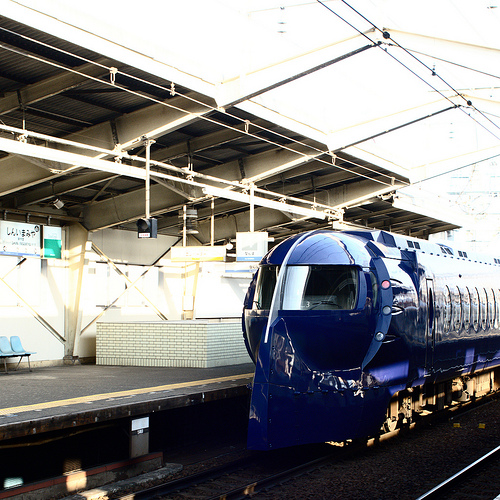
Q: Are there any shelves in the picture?
A: No, there are no shelves.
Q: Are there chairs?
A: Yes, there is a chair.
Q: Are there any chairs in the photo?
A: Yes, there is a chair.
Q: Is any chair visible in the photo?
A: Yes, there is a chair.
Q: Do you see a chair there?
A: Yes, there is a chair.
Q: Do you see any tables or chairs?
A: Yes, there is a chair.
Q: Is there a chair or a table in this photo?
A: Yes, there is a chair.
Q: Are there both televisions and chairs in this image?
A: No, there is a chair but no televisions.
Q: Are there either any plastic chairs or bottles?
A: Yes, there is a plastic chair.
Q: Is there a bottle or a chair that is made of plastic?
A: Yes, the chair is made of plastic.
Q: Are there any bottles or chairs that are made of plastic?
A: Yes, the chair is made of plastic.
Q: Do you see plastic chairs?
A: Yes, there is a chair that is made of plastic.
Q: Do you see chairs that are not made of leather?
A: Yes, there is a chair that is made of plastic.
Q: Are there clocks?
A: No, there are no clocks.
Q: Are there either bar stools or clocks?
A: No, there are no clocks or bar stools.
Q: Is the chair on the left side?
A: Yes, the chair is on the left of the image.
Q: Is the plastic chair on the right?
A: No, the chair is on the left of the image.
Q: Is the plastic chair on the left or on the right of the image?
A: The chair is on the left of the image.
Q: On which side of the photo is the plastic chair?
A: The chair is on the left of the image.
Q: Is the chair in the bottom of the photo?
A: Yes, the chair is in the bottom of the image.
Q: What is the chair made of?
A: The chair is made of plastic.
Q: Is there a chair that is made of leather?
A: No, there is a chair but it is made of plastic.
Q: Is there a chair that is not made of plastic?
A: No, there is a chair but it is made of plastic.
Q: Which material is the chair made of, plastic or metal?
A: The chair is made of plastic.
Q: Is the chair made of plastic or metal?
A: The chair is made of plastic.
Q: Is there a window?
A: Yes, there is a window.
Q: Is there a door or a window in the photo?
A: Yes, there is a window.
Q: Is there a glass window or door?
A: Yes, there is a glass window.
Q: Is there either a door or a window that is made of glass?
A: Yes, the window is made of glass.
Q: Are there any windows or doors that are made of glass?
A: Yes, the window is made of glass.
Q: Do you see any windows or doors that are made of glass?
A: Yes, the window is made of glass.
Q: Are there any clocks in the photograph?
A: No, there are no clocks.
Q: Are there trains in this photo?
A: Yes, there is a train.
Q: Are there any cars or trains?
A: Yes, there is a train.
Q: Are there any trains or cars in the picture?
A: Yes, there is a train.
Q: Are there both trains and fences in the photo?
A: No, there is a train but no fences.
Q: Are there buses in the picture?
A: No, there are no buses.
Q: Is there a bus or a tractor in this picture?
A: No, there are no buses or tractors.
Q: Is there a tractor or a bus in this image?
A: No, there are no buses or tractors.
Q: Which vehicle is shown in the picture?
A: The vehicle is a train.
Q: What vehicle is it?
A: The vehicle is a train.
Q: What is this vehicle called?
A: This is a train.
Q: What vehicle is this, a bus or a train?
A: This is a train.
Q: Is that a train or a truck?
A: That is a train.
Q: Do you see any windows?
A: Yes, there is a window.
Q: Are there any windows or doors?
A: Yes, there is a window.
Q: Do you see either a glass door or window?
A: Yes, there is a glass window.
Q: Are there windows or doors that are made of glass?
A: Yes, the window is made of glass.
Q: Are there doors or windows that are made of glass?
A: Yes, the window is made of glass.